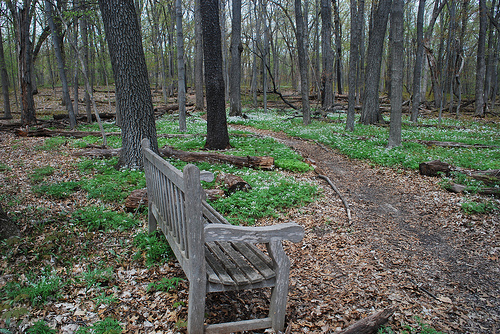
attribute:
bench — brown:
[109, 126, 359, 331]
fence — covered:
[0, 87, 498, 122]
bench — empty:
[136, 133, 316, 318]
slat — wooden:
[211, 253, 281, 287]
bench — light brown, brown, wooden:
[133, 137, 309, 332]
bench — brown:
[150, 145, 262, 330]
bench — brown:
[51, 91, 353, 318]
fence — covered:
[67, 84, 387, 176]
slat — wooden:
[184, 208, 244, 269]